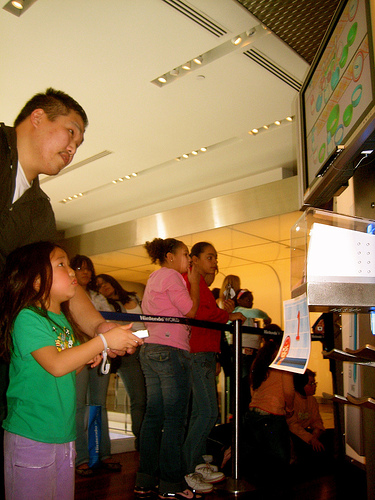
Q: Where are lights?
A: On the ceiling.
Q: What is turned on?
A: TV screen.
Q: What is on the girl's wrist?
A: Strap for Wii controller.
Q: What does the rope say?
A: Nintendo.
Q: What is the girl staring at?
A: TV screen.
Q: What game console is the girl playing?
A: Wii.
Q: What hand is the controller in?
A: Right.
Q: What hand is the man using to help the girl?
A: Left.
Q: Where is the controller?
A: In her hand.